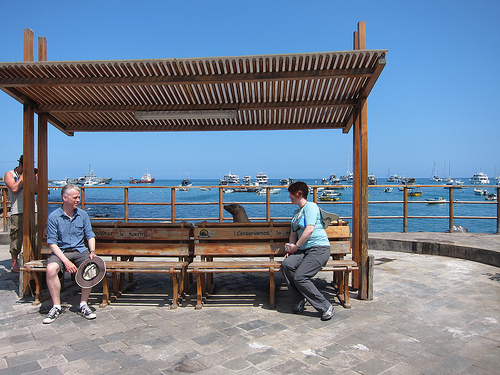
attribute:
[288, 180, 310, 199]
hair — short, dark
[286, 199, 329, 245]
shirt — blue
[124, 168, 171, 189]
boat — white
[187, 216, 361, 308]
bench — brown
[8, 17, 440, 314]
structure — brown, wooden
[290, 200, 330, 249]
shirt — blue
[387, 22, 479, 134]
sky — clear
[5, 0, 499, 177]
sky — blue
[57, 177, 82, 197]
hair — salt and pepper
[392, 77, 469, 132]
sky — clear, blue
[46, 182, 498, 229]
railing — large, brass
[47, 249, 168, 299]
shorts — grey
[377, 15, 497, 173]
sky — blue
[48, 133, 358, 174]
sky — blue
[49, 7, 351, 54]
sky — blue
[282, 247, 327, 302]
pants — grey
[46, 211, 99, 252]
shirt — blue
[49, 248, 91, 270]
shorts — brown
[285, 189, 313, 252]
skin — fair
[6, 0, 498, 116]
sky — blue